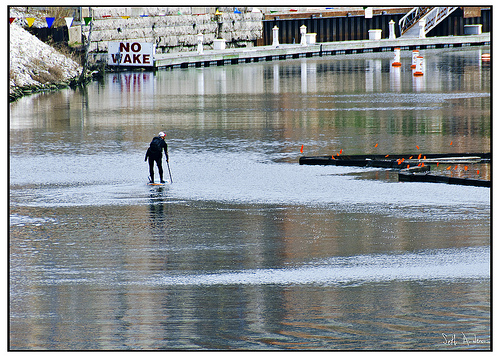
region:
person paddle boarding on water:
[141, 127, 179, 192]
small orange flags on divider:
[332, 144, 404, 165]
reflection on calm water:
[264, 71, 373, 95]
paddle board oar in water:
[166, 162, 177, 187]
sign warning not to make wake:
[97, 37, 157, 71]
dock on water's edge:
[269, 34, 404, 66]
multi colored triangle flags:
[21, 12, 143, 32]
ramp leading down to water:
[390, 8, 448, 46]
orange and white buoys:
[383, 47, 427, 84]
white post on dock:
[263, 23, 285, 56]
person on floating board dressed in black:
[133, 115, 198, 208]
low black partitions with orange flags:
[276, 130, 481, 195]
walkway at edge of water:
[121, 21, 478, 71]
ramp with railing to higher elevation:
[391, 1, 452, 36]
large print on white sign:
[100, 35, 170, 72]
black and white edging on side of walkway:
[181, 36, 481, 61]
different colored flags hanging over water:
[10, 5, 245, 27]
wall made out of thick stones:
[92, 10, 239, 41]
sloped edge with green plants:
[10, 20, 90, 101]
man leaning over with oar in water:
[127, 120, 199, 195]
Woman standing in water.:
[142, 131, 174, 188]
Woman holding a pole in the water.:
[142, 125, 176, 191]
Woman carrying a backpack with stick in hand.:
[111, 112, 204, 208]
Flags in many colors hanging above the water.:
[6, 5, 343, 33]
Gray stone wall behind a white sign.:
[80, 10, 262, 62]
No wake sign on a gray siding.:
[100, 35, 160, 72]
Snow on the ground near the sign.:
[10, 20, 83, 89]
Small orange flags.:
[297, 139, 489, 185]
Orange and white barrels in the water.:
[382, 48, 491, 76]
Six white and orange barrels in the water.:
[383, 40, 434, 90]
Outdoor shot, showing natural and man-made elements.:
[17, 13, 494, 349]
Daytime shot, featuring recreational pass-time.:
[12, 1, 487, 352]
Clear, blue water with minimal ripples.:
[73, 221, 478, 334]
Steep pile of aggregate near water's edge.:
[7, 20, 77, 98]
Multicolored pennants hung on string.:
[7, 2, 122, 27]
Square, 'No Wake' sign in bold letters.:
[110, 35, 161, 84]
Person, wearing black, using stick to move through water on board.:
[125, 115, 188, 190]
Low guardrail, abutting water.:
[191, 35, 477, 56]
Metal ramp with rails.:
[400, 1, 451, 37]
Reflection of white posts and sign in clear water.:
[127, 56, 367, 94]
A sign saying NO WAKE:
[98, 36, 213, 88]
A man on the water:
[137, 110, 248, 238]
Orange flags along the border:
[273, 104, 492, 219]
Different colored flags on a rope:
[21, 12, 286, 34]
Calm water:
[42, 95, 322, 351]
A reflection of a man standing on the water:
[127, 177, 204, 237]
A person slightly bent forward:
[125, 122, 191, 172]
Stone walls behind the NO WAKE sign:
[88, 15, 283, 50]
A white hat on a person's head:
[152, 126, 172, 149]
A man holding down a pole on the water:
[148, 121, 205, 211]